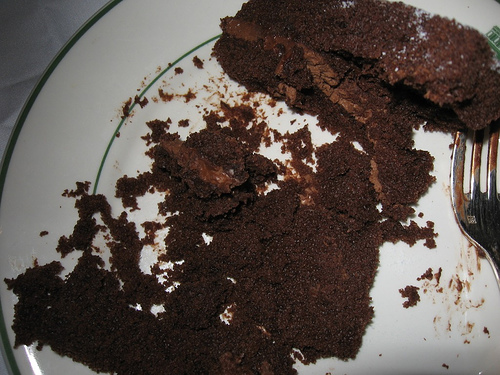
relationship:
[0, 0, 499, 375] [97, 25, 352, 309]
plate has chocolate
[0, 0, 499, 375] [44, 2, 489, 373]
plate has cake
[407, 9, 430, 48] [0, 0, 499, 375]
powder on cake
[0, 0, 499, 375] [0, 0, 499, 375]
cake on plate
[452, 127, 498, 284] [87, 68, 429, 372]
fork with chocolate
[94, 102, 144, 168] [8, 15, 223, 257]
marking on plate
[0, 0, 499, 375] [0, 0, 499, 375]
cake smashed on plate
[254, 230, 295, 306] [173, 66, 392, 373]
chocolate filling in cake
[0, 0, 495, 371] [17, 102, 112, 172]
brownie on a plate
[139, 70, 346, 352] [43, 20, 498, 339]
cake on a plate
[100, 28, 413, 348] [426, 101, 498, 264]
brownie on a fork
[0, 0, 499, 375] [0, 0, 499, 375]
cake crusted on a plate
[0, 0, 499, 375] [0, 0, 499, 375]
cake on a plate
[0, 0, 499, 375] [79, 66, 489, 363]
cake smeared over a plate